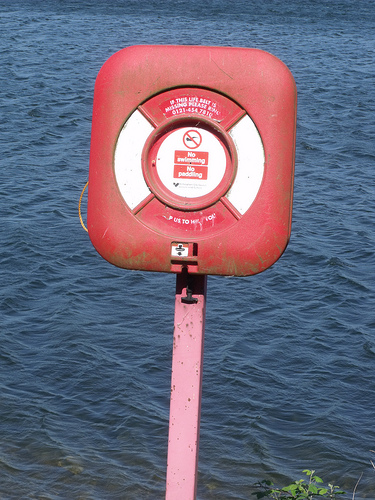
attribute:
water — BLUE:
[236, 334, 323, 442]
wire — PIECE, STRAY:
[77, 181, 91, 234]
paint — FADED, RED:
[169, 306, 194, 481]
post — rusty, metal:
[162, 271, 205, 499]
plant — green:
[258, 465, 345, 499]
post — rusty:
[154, 275, 211, 497]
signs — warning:
[168, 123, 211, 183]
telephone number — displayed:
[161, 94, 223, 119]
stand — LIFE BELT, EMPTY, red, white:
[82, 38, 302, 284]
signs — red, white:
[170, 146, 210, 182]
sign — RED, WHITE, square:
[79, 35, 301, 283]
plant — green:
[251, 462, 346, 498]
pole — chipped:
[159, 274, 210, 498]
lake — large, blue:
[3, 4, 373, 498]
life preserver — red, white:
[82, 41, 301, 289]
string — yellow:
[69, 178, 84, 231]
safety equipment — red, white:
[80, 39, 301, 284]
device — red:
[83, 36, 301, 498]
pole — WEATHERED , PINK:
[159, 270, 214, 495]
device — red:
[81, 36, 301, 285]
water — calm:
[5, 5, 369, 499]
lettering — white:
[160, 93, 227, 119]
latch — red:
[130, 217, 230, 307]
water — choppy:
[285, 307, 312, 364]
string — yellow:
[48, 179, 103, 246]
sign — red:
[182, 127, 219, 186]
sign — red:
[171, 157, 213, 191]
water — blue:
[26, 56, 113, 134]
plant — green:
[305, 467, 337, 497]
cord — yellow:
[64, 167, 95, 233]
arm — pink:
[163, 277, 215, 479]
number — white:
[156, 92, 222, 117]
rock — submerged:
[62, 448, 94, 481]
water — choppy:
[285, 43, 364, 146]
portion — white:
[223, 116, 259, 201]